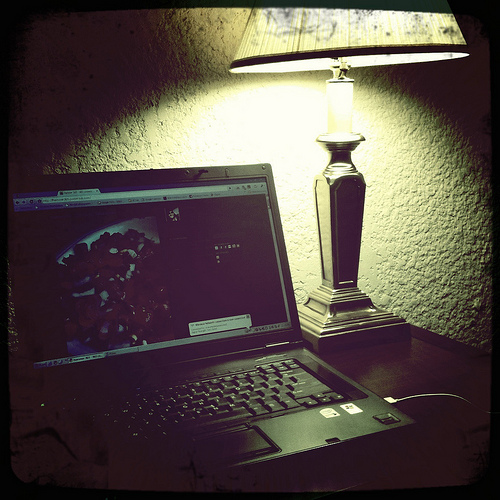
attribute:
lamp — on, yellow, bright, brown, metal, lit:
[254, 17, 458, 152]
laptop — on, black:
[41, 180, 314, 444]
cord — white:
[413, 385, 449, 407]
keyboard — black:
[152, 373, 302, 427]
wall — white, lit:
[78, 30, 204, 100]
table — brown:
[399, 325, 454, 370]